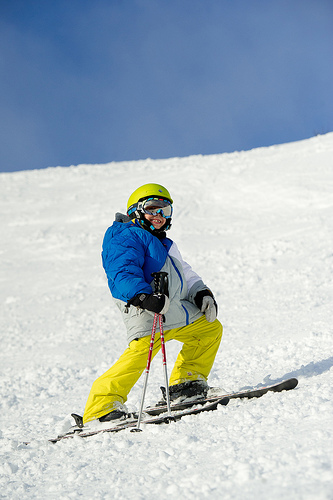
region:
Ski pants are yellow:
[83, 313, 223, 422]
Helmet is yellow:
[124, 183, 172, 210]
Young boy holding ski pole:
[79, 183, 225, 420]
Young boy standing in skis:
[81, 182, 224, 429]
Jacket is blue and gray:
[103, 215, 215, 339]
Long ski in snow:
[66, 377, 306, 422]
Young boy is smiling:
[82, 181, 224, 423]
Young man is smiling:
[81, 181, 223, 422]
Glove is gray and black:
[193, 285, 220, 323]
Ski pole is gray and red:
[158, 269, 176, 415]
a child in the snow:
[81, 179, 213, 446]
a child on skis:
[52, 178, 297, 449]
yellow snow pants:
[71, 314, 221, 425]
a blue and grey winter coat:
[91, 209, 216, 340]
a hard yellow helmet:
[120, 181, 173, 229]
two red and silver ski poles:
[130, 264, 178, 436]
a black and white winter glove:
[145, 291, 168, 313]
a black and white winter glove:
[197, 292, 217, 315]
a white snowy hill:
[11, 129, 332, 495]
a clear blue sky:
[0, 3, 331, 143]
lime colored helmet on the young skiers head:
[126, 181, 175, 210]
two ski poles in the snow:
[130, 301, 179, 433]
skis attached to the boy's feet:
[21, 375, 295, 443]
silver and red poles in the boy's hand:
[130, 292, 181, 433]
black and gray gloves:
[189, 282, 224, 321]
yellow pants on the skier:
[85, 314, 225, 419]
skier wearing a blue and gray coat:
[100, 180, 225, 345]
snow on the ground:
[4, 432, 330, 499]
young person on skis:
[42, 180, 302, 443]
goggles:
[139, 198, 181, 217]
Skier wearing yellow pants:
[94, 305, 258, 429]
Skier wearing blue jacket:
[96, 219, 232, 316]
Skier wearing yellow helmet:
[110, 186, 195, 245]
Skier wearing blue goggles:
[129, 197, 178, 224]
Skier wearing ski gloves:
[126, 288, 228, 319]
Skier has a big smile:
[134, 202, 179, 235]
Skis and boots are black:
[55, 359, 328, 464]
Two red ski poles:
[128, 266, 194, 452]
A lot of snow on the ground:
[49, 165, 311, 456]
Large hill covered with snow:
[101, 124, 323, 444]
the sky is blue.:
[0, 0, 331, 154]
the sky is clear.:
[1, 0, 331, 140]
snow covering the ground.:
[0, 129, 332, 498]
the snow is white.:
[0, 132, 332, 498]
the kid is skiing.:
[47, 176, 297, 445]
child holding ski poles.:
[127, 270, 175, 436]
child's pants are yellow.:
[78, 303, 224, 427]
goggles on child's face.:
[139, 194, 178, 212]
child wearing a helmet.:
[123, 177, 170, 229]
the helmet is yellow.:
[124, 177, 176, 217]